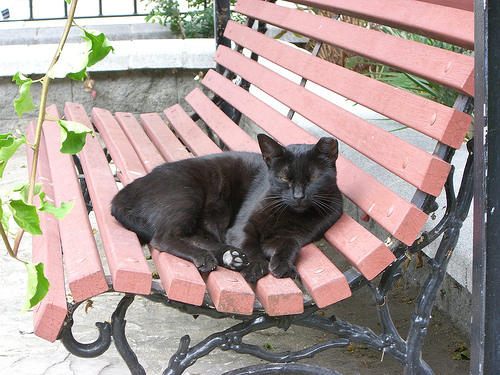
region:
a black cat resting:
[110, 131, 345, 283]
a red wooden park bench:
[21, 0, 478, 374]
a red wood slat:
[21, 120, 67, 343]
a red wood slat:
[38, 100, 107, 302]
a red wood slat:
[62, 99, 152, 296]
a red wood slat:
[89, 105, 206, 307]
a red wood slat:
[139, 112, 306, 318]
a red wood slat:
[184, 86, 398, 279]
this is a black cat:
[77, 123, 358, 289]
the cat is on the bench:
[92, 97, 410, 274]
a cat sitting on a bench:
[82, 111, 375, 298]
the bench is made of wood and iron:
[15, 11, 451, 371]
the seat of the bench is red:
[15, 75, 395, 335]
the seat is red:
[30, 50, 415, 350]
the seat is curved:
[17, 46, 457, 342]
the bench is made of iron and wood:
[5, 0, 475, 338]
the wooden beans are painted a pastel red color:
[0, 0, 488, 350]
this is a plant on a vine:
[9, 10, 114, 309]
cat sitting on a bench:
[88, 136, 363, 276]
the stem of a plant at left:
[5, 3, 100, 310]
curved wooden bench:
[25, 0, 490, 320]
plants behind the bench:
[302, 0, 478, 120]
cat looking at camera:
[100, 130, 345, 285]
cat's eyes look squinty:
[276, 170, 316, 182]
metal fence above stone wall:
[0, 0, 221, 35]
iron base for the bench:
[64, 188, 471, 373]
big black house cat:
[114, 127, 351, 287]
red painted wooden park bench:
[22, 5, 484, 371]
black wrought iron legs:
[60, 284, 442, 374]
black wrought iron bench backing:
[371, 138, 476, 373]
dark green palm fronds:
[336, 7, 496, 167]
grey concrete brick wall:
[0, 70, 291, 160]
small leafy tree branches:
[136, 1, 220, 38]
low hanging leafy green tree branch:
[0, 0, 120, 320]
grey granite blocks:
[3, 20, 475, 292]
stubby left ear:
[309, 133, 343, 162]